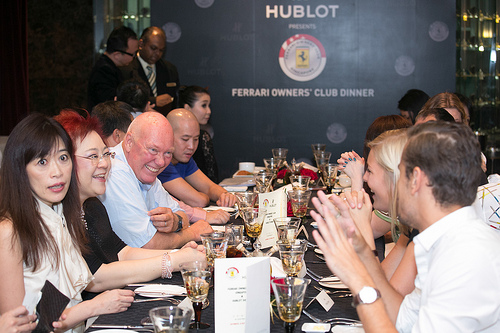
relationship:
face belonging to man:
[130, 122, 175, 182] [97, 108, 214, 251]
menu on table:
[223, 257, 267, 331] [123, 307, 142, 321]